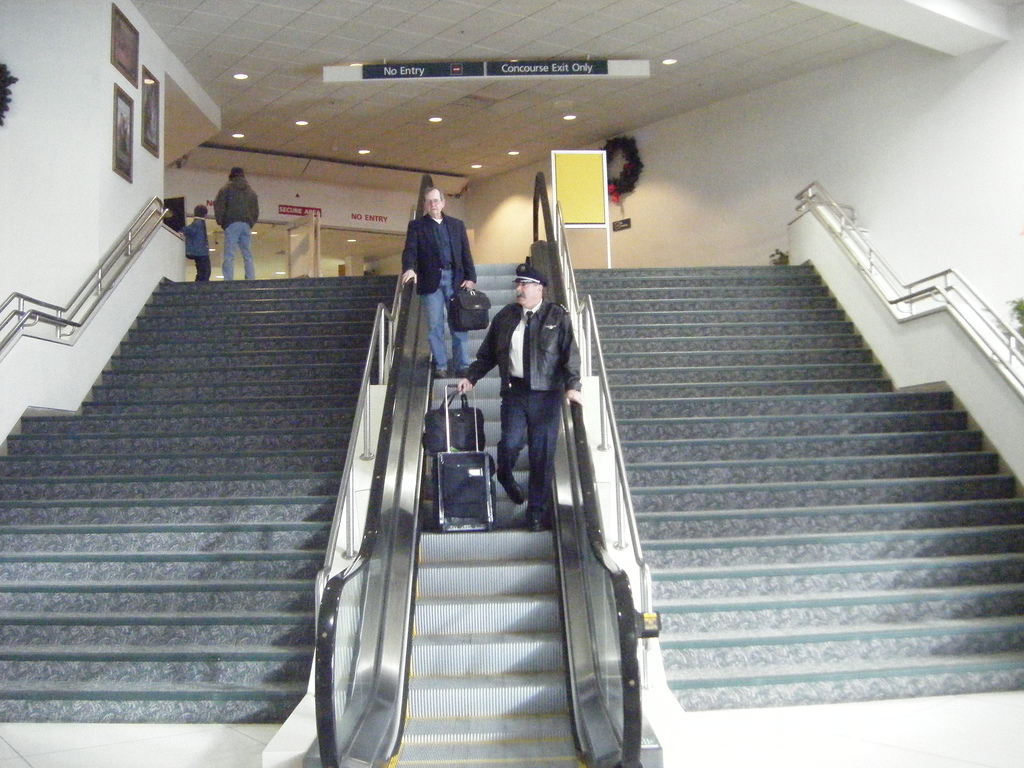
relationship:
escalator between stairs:
[313, 170, 656, 758] [593, 261, 1021, 640]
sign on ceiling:
[344, 49, 624, 87] [146, 2, 879, 104]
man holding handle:
[446, 260, 580, 530] [442, 367, 494, 465]